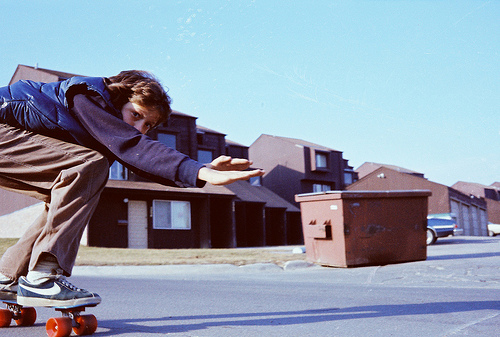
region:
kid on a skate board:
[1, 57, 266, 334]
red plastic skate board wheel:
[31, 307, 73, 334]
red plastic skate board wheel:
[74, 307, 99, 335]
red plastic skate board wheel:
[13, 297, 40, 332]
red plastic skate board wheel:
[0, 302, 15, 333]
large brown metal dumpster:
[290, 182, 436, 274]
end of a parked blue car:
[423, 201, 465, 252]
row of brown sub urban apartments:
[6, 54, 498, 253]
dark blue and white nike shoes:
[11, 271, 105, 316]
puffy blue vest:
[2, 68, 128, 148]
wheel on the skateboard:
[44, 317, 68, 335]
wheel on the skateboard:
[76, 313, 101, 335]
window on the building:
[148, 196, 198, 233]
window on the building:
[316, 152, 328, 171]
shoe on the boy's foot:
[12, 275, 98, 309]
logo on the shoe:
[18, 284, 65, 299]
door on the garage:
[443, 194, 463, 234]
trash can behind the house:
[293, 184, 435, 273]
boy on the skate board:
[0, 47, 270, 333]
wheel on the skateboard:
[13, 304, 38, 324]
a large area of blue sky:
[0, 0, 499, 187]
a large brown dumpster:
[293, 188, 432, 268]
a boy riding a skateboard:
[0, 69, 265, 305]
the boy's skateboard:
[0, 298, 100, 335]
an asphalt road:
[0, 275, 499, 335]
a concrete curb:
[72, 258, 322, 275]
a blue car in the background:
[426, 217, 463, 245]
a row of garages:
[344, 165, 489, 235]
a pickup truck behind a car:
[427, 211, 457, 222]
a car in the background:
[487, 220, 499, 237]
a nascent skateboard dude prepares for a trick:
[2, 50, 272, 333]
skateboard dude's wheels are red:
[1, 297, 104, 335]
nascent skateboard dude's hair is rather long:
[101, 64, 178, 139]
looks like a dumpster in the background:
[286, 180, 438, 270]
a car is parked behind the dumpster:
[427, 202, 464, 249]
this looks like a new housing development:
[3, 57, 312, 264]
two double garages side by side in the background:
[439, 183, 496, 243]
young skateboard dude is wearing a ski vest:
[0, 72, 120, 148]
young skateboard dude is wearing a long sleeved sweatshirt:
[61, 75, 216, 197]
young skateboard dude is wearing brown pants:
[2, 118, 117, 284]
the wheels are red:
[34, 305, 113, 332]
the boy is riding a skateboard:
[1, 256, 114, 331]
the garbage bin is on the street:
[272, 152, 442, 283]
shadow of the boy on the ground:
[140, 282, 460, 327]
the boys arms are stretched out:
[2, 35, 273, 245]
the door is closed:
[112, 191, 158, 253]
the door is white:
[107, 187, 156, 256]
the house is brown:
[41, 75, 256, 261]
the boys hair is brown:
[98, 59, 177, 139]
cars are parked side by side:
[395, 197, 469, 261]